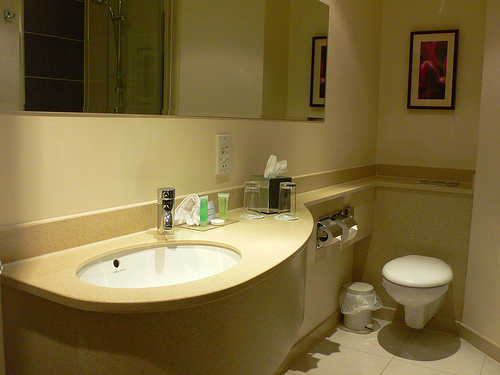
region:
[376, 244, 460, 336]
toilet in a bathroom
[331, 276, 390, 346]
trash can in a bathroom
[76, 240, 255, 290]
sink in a bathroom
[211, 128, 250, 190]
outlet on a wall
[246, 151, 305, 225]
tissue box on counter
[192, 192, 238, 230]
soaps on a counter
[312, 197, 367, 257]
toilet paper in a bathroom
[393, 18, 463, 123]
picture frame on wall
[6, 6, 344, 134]
mirror on a wall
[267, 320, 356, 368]
shadows on the ground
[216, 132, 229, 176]
socket on a wall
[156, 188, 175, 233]
faucet on a sink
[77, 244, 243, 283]
a white sink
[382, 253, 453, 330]
a toilet on a bathroom wall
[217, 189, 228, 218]
a small bottle of soap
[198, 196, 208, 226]
a small bottle of soap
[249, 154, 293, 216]
a box of tissues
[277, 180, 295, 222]
a cup is upside down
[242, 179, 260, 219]
a cup is upside down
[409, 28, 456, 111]
a painting on a wall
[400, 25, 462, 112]
a picture hanging on the wall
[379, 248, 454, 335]
a closed white toilet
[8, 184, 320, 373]
a clean bathroom counter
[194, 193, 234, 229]
two green shampoo bottles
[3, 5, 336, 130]
a large mirror hanging above the sink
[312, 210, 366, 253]
two toilet paper rolls next to the toilet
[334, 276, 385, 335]
a small trash can next to the toilet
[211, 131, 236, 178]
a white outlet on the wall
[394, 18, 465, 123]
Picture on the wall.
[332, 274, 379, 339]
Garbage can on the floor.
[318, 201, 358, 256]
Rolls of paper on the wall.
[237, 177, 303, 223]
Two clear drinking glasses.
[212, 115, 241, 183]
Outlets on the wall.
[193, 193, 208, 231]
Shampoo on the sink.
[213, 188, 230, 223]
Hand wash on the sink.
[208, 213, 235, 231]
Bar of soap on the desk.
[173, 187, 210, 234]
Small towel on the sink.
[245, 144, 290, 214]
Box of tissues on the desk.